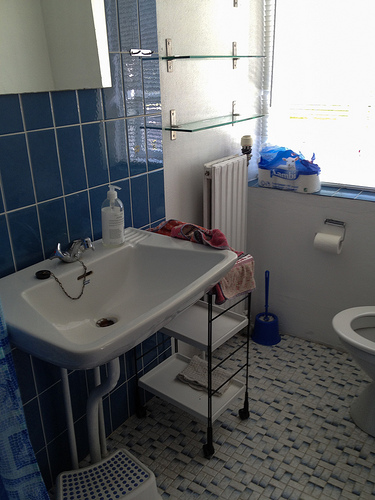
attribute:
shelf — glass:
[161, 113, 267, 133]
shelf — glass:
[154, 53, 269, 59]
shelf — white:
[135, 297, 251, 429]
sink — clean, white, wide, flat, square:
[0, 207, 238, 372]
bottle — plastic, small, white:
[98, 184, 129, 247]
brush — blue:
[251, 269, 284, 345]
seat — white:
[330, 301, 375, 360]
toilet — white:
[331, 301, 374, 442]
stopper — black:
[35, 269, 53, 281]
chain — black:
[50, 258, 87, 301]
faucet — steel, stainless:
[47, 238, 97, 267]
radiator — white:
[202, 153, 253, 333]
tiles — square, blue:
[54, 323, 373, 498]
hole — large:
[93, 315, 119, 329]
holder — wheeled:
[130, 249, 259, 458]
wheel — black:
[238, 407, 250, 422]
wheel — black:
[134, 406, 150, 421]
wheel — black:
[200, 443, 216, 459]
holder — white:
[312, 219, 351, 253]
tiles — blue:
[0, 2, 173, 499]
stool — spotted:
[55, 443, 163, 500]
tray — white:
[137, 349, 248, 424]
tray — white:
[159, 299, 253, 353]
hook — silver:
[130, 47, 155, 59]